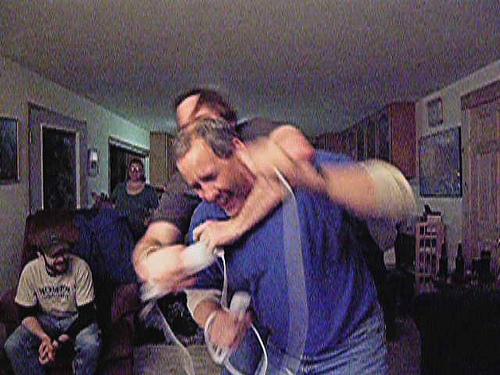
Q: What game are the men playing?
A: Wii.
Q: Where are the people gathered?
A: In a home.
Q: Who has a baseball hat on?
A: The seated man.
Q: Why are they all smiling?
A: They are having fun.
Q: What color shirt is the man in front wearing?
A: Blue.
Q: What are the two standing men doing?
A: Wrestling.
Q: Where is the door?
A: On the right.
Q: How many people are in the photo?
A: 4.